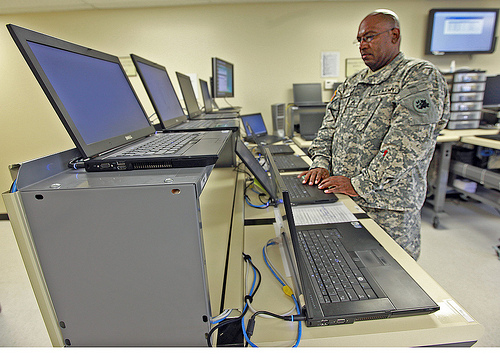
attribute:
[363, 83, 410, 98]
tag — green